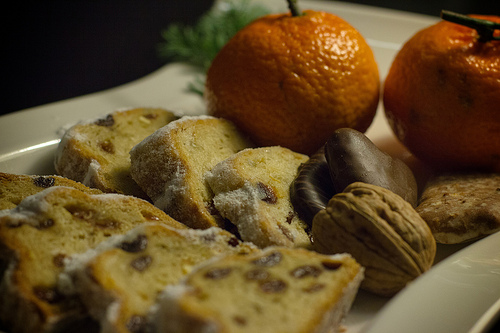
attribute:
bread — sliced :
[4, 108, 371, 327]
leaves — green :
[163, 56, 216, 125]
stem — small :
[280, 1, 312, 22]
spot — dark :
[116, 227, 157, 280]